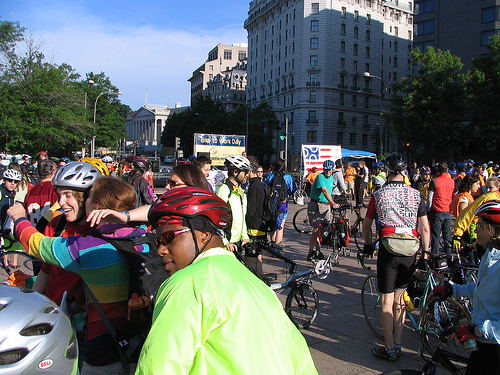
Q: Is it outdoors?
A: Yes, it is outdoors.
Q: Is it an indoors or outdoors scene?
A: It is outdoors.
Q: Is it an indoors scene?
A: No, it is outdoors.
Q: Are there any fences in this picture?
A: No, there are no fences.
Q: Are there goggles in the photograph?
A: Yes, there are goggles.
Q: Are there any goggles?
A: Yes, there are goggles.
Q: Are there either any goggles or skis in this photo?
A: Yes, there are goggles.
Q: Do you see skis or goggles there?
A: Yes, there are goggles.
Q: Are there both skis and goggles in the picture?
A: No, there are goggles but no skis.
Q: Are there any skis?
A: No, there are no skis.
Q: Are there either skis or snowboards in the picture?
A: No, there are no skis or snowboards.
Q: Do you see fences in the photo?
A: No, there are no fences.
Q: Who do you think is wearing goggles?
A: The man is wearing goggles.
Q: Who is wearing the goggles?
A: The man is wearing goggles.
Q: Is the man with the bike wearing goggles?
A: Yes, the man is wearing goggles.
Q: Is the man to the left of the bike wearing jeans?
A: No, the man is wearing goggles.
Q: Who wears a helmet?
A: The man wears a helmet.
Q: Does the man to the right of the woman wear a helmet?
A: Yes, the man wears a helmet.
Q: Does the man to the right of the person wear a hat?
A: No, the man wears a helmet.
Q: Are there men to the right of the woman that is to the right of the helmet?
A: Yes, there is a man to the right of the woman.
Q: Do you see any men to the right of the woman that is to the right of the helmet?
A: Yes, there is a man to the right of the woman.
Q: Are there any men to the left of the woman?
A: No, the man is to the right of the woman.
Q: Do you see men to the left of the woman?
A: No, the man is to the right of the woman.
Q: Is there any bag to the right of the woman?
A: No, there is a man to the right of the woman.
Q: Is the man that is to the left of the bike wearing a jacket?
A: Yes, the man is wearing a jacket.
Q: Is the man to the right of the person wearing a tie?
A: No, the man is wearing a jacket.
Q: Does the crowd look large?
A: Yes, the crowd is large.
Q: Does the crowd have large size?
A: Yes, the crowd is large.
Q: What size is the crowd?
A: The crowd is large.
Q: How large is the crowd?
A: The crowd is large.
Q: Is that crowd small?
A: No, the crowd is large.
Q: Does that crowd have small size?
A: No, the crowd is large.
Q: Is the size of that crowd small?
A: No, the crowd is large.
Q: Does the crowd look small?
A: No, the crowd is large.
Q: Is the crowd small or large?
A: The crowd is large.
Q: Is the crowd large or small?
A: The crowd is large.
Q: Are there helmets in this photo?
A: Yes, there is a helmet.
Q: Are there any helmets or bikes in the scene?
A: Yes, there is a helmet.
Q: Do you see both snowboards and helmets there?
A: No, there is a helmet but no snowboards.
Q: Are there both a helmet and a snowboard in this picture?
A: No, there is a helmet but no snowboards.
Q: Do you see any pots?
A: No, there are no pots.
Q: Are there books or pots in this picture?
A: No, there are no pots or books.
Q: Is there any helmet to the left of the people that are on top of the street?
A: Yes, there is a helmet to the left of the people.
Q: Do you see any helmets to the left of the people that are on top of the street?
A: Yes, there is a helmet to the left of the people.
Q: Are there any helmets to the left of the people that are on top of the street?
A: Yes, there is a helmet to the left of the people.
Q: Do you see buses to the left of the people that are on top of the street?
A: No, there is a helmet to the left of the people.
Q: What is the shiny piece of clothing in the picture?
A: The clothing item is a jacket.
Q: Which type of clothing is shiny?
A: The clothing is a jacket.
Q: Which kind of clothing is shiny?
A: The clothing is a jacket.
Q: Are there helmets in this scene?
A: Yes, there is a helmet.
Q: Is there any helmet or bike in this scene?
A: Yes, there is a helmet.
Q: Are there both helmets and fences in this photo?
A: No, there is a helmet but no fences.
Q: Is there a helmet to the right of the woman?
A: Yes, there is a helmet to the right of the woman.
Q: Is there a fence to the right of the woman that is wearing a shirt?
A: No, there is a helmet to the right of the woman.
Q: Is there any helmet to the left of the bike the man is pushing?
A: Yes, there is a helmet to the left of the bike.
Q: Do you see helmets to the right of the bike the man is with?
A: No, the helmet is to the left of the bike.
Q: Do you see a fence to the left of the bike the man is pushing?
A: No, there is a helmet to the left of the bike.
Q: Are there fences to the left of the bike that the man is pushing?
A: No, there is a helmet to the left of the bike.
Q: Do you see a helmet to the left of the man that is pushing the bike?
A: Yes, there is a helmet to the left of the man.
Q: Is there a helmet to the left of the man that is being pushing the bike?
A: Yes, there is a helmet to the left of the man.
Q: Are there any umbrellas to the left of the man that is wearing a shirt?
A: No, there is a helmet to the left of the man.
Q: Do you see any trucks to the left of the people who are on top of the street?
A: No, there is a helmet to the left of the people.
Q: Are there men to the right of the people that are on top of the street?
A: Yes, there is a man to the right of the people.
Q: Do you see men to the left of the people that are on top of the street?
A: No, the man is to the right of the people.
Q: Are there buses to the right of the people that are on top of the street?
A: No, there is a man to the right of the people.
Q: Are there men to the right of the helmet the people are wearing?
A: Yes, there is a man to the right of the helmet.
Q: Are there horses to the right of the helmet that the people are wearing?
A: No, there is a man to the right of the helmet.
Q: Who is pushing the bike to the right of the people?
A: The man is pushing the bike.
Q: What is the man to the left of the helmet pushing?
A: The man is pushing the bike.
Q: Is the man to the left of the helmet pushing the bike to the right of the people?
A: Yes, the man is pushing the bike.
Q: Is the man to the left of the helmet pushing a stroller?
A: No, the man is pushing the bike.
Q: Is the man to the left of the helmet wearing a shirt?
A: Yes, the man is wearing a shirt.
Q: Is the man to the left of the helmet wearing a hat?
A: No, the man is wearing a shirt.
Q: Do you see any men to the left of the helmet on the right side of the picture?
A: Yes, there is a man to the left of the helmet.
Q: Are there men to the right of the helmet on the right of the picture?
A: No, the man is to the left of the helmet.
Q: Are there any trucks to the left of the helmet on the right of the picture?
A: No, there is a man to the left of the helmet.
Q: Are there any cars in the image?
A: No, there are no cars.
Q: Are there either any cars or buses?
A: No, there are no cars or buses.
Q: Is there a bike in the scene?
A: Yes, there is a bike.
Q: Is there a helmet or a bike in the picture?
A: Yes, there is a bike.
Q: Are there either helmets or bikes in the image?
A: Yes, there is a bike.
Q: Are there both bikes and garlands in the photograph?
A: No, there is a bike but no garlands.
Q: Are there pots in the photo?
A: No, there are no pots.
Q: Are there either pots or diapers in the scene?
A: No, there are no pots or diapers.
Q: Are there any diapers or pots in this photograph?
A: No, there are no pots or diapers.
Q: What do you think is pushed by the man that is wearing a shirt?
A: The bike is pushed by the man.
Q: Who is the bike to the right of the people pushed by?
A: The bike is pushed by the man.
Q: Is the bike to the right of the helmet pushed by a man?
A: Yes, the bike is pushed by a man.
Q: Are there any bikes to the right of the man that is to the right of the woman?
A: Yes, there is a bike to the right of the man.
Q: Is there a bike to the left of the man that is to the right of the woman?
A: No, the bike is to the right of the man.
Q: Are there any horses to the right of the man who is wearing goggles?
A: No, there is a bike to the right of the man.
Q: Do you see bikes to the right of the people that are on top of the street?
A: Yes, there is a bike to the right of the people.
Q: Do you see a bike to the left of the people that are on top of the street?
A: No, the bike is to the right of the people.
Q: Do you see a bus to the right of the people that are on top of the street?
A: No, there is a bike to the right of the people.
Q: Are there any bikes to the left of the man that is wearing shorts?
A: Yes, there is a bike to the left of the man.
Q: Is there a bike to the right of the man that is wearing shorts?
A: No, the bike is to the left of the man.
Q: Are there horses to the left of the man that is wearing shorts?
A: No, there is a bike to the left of the man.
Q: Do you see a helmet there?
A: Yes, there is a helmet.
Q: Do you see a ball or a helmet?
A: Yes, there is a helmet.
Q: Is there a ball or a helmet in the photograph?
A: Yes, there is a helmet.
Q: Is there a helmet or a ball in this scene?
A: Yes, there is a helmet.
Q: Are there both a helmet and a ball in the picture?
A: No, there is a helmet but no balls.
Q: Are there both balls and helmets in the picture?
A: No, there is a helmet but no balls.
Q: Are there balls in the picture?
A: No, there are no balls.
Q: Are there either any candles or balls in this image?
A: No, there are no balls or candles.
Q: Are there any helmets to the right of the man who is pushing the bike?
A: Yes, there is a helmet to the right of the man.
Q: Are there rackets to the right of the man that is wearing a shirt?
A: No, there is a helmet to the right of the man.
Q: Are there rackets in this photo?
A: No, there are no rackets.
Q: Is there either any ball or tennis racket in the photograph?
A: No, there are no rackets or balls.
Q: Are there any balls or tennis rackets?
A: No, there are no tennis rackets or balls.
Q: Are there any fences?
A: No, there are no fences.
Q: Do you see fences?
A: No, there are no fences.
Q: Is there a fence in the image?
A: No, there are no fences.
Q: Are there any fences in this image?
A: No, there are no fences.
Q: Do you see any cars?
A: No, there are no cars.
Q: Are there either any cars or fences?
A: No, there are no cars or fences.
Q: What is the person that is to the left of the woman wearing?
A: The person is wearing a helmet.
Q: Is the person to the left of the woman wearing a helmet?
A: Yes, the person is wearing a helmet.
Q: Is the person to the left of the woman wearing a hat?
A: No, the person is wearing a helmet.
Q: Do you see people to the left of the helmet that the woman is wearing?
A: Yes, there is a person to the left of the helmet.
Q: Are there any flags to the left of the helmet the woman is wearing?
A: No, there is a person to the left of the helmet.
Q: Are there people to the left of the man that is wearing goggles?
A: Yes, there is a person to the left of the man.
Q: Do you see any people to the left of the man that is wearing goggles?
A: Yes, there is a person to the left of the man.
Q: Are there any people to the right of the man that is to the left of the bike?
A: No, the person is to the left of the man.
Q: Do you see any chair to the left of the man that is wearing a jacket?
A: No, there is a person to the left of the man.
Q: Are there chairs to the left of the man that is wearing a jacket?
A: No, there is a person to the left of the man.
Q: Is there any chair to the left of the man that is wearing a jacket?
A: No, there is a person to the left of the man.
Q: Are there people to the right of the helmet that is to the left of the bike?
A: No, the person is to the left of the helmet.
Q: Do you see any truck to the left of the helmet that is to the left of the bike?
A: No, there is a person to the left of the helmet.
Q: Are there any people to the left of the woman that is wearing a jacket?
A: Yes, there is a person to the left of the woman.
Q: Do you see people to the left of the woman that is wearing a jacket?
A: Yes, there is a person to the left of the woman.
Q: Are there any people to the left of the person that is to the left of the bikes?
A: Yes, there is a person to the left of the woman.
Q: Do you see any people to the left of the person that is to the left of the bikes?
A: Yes, there is a person to the left of the woman.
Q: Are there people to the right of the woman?
A: No, the person is to the left of the woman.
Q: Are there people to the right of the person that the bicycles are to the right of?
A: No, the person is to the left of the woman.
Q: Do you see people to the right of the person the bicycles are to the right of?
A: No, the person is to the left of the woman.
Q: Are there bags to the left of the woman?
A: No, there is a person to the left of the woman.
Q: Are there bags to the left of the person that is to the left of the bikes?
A: No, there is a person to the left of the woman.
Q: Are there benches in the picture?
A: No, there are no benches.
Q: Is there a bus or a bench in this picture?
A: No, there are no benches or buses.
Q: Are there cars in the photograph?
A: No, there are no cars.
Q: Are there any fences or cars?
A: No, there are no cars or fences.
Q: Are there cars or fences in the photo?
A: No, there are no cars or fences.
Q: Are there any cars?
A: No, there are no cars.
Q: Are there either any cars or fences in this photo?
A: No, there are no cars or fences.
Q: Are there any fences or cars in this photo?
A: No, there are no cars or fences.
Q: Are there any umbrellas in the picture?
A: No, there are no umbrellas.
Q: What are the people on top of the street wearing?
A: The people are wearing a helmet.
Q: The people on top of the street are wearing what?
A: The people are wearing a helmet.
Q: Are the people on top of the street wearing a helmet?
A: Yes, the people are wearing a helmet.